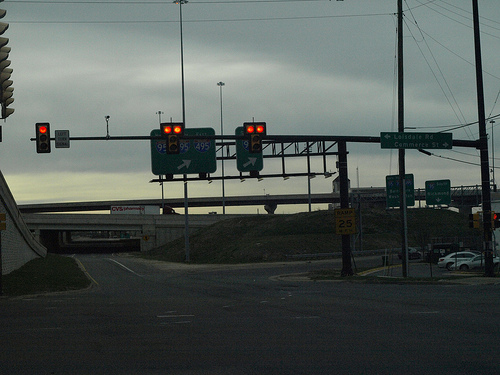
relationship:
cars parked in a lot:
[439, 249, 485, 272] [373, 239, 499, 287]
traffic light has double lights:
[159, 121, 186, 155] [160, 121, 188, 137]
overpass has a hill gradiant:
[18, 191, 343, 223] [149, 213, 337, 263]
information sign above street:
[151, 130, 218, 176] [79, 254, 342, 371]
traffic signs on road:
[384, 174, 453, 209] [27, 210, 224, 251]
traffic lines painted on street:
[106, 252, 153, 283] [79, 254, 342, 371]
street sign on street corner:
[380, 131, 455, 151] [309, 249, 406, 301]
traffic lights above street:
[244, 121, 269, 155] [79, 254, 342, 371]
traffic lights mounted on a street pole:
[244, 121, 269, 155] [26, 125, 480, 148]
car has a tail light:
[439, 249, 485, 272] [440, 257, 446, 264]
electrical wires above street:
[6, 7, 403, 27] [79, 254, 342, 371]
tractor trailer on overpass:
[110, 201, 183, 217] [18, 191, 343, 223]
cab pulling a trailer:
[163, 204, 179, 218] [110, 202, 161, 216]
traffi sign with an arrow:
[236, 127, 266, 172] [243, 154, 258, 173]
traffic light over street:
[159, 121, 186, 155] [79, 254, 342, 371]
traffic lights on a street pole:
[244, 121, 269, 155] [26, 125, 480, 148]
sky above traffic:
[8, 0, 500, 123] [1, 176, 499, 374]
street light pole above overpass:
[173, 0, 196, 266] [18, 191, 343, 223]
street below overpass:
[59, 234, 398, 374] [18, 191, 343, 223]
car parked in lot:
[439, 249, 485, 272] [373, 239, 499, 287]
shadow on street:
[71, 236, 138, 256] [59, 234, 398, 374]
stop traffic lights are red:
[244, 121, 269, 155] [244, 120, 269, 140]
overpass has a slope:
[18, 191, 343, 223] [149, 213, 337, 263]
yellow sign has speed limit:
[335, 207, 359, 238] [339, 215, 353, 231]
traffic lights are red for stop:
[244, 121, 269, 155] [244, 120, 269, 140]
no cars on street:
[59, 234, 398, 374] [79, 254, 342, 371]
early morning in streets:
[2, 1, 500, 374] [1, 176, 499, 374]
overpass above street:
[18, 191, 343, 223] [79, 254, 342, 371]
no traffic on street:
[1, 215, 498, 372] [79, 254, 342, 371]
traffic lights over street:
[244, 121, 269, 155] [79, 254, 342, 371]